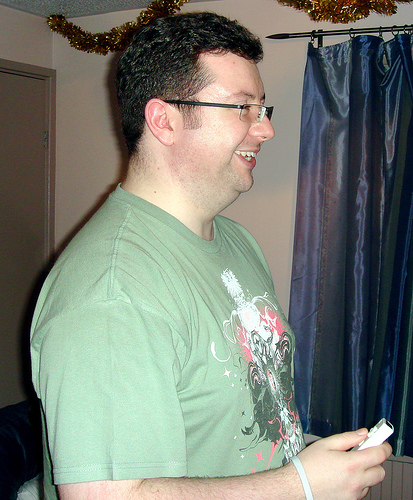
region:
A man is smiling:
[98, 6, 292, 227]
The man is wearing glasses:
[151, 77, 284, 149]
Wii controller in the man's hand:
[294, 375, 401, 494]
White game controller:
[320, 386, 404, 487]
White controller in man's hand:
[336, 409, 402, 483]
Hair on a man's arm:
[193, 459, 284, 492]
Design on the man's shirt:
[194, 261, 309, 448]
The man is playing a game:
[29, 10, 403, 493]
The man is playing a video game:
[27, 9, 402, 491]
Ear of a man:
[137, 89, 183, 153]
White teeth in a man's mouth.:
[235, 149, 256, 161]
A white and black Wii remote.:
[348, 419, 394, 450]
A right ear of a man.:
[144, 97, 177, 145]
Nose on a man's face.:
[250, 113, 275, 144]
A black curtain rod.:
[264, 24, 411, 42]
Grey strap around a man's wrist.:
[290, 453, 314, 499]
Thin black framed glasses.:
[160, 99, 273, 119]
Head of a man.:
[114, 11, 276, 193]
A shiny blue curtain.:
[288, 31, 411, 459]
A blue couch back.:
[0, 398, 43, 498]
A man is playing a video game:
[22, 5, 398, 496]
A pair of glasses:
[159, 88, 273, 124]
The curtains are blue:
[280, 27, 406, 459]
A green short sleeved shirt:
[22, 177, 312, 496]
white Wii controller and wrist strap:
[289, 418, 392, 499]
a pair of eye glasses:
[162, 101, 274, 121]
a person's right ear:
[142, 98, 177, 146]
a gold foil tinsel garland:
[48, 2, 186, 56]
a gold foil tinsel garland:
[280, 0, 409, 23]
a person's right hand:
[287, 426, 391, 497]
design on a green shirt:
[208, 268, 304, 471]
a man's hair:
[116, 11, 262, 157]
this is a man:
[26, 14, 410, 497]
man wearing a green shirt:
[25, 167, 319, 495]